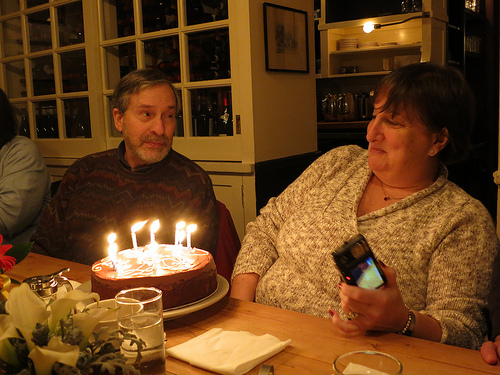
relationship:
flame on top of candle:
[129, 219, 149, 229] [129, 231, 137, 250]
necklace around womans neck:
[375, 181, 406, 205] [351, 165, 440, 196]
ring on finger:
[346, 313, 354, 323] [339, 302, 363, 322]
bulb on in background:
[361, 20, 376, 35] [314, 1, 442, 143]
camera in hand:
[328, 222, 395, 298] [343, 261, 408, 331]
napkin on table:
[171, 315, 296, 373] [5, 249, 498, 371]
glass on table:
[109, 284, 172, 370] [18, 236, 325, 352]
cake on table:
[88, 217, 253, 312] [5, 249, 498, 371]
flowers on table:
[7, 253, 95, 283] [269, 316, 341, 354]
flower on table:
[3, 229, 24, 299] [5, 249, 498, 371]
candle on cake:
[174, 231, 188, 267] [87, 239, 219, 308]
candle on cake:
[172, 216, 182, 245] [91, 243, 218, 310]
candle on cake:
[187, 221, 198, 251] [91, 243, 218, 310]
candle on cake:
[148, 217, 161, 246] [91, 243, 218, 310]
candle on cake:
[132, 232, 138, 248] [91, 243, 218, 310]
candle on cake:
[109, 242, 119, 269] [91, 243, 218, 310]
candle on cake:
[174, 230, 179, 245] [91, 243, 218, 310]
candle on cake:
[132, 232, 138, 248] [86, 238, 230, 312]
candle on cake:
[127, 217, 147, 249] [87, 240, 220, 314]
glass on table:
[328, 338, 410, 373] [1, 224, 499, 371]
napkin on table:
[166, 328, 292, 375] [2, 245, 469, 373]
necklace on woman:
[383, 181, 405, 201] [216, 40, 488, 347]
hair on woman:
[406, 66, 458, 113] [226, 65, 471, 327]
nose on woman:
[365, 115, 385, 142] [230, 60, 499, 348]